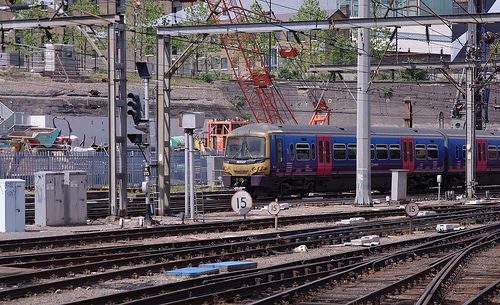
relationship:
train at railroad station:
[221, 125, 496, 196] [3, 3, 493, 300]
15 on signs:
[233, 195, 247, 211] [212, 171, 439, 232]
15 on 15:
[267, 204, 277, 216] [267, 204, 277, 216]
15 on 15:
[406, 204, 416, 218] [406, 204, 416, 218]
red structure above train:
[207, 12, 341, 114] [206, 115, 498, 195]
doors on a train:
[308, 131, 338, 177] [221, 125, 496, 196]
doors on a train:
[400, 129, 420, 171] [221, 125, 496, 196]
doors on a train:
[475, 136, 487, 175] [221, 125, 496, 196]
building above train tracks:
[334, 2, 485, 92] [46, 228, 495, 303]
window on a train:
[295, 143, 311, 160] [221, 125, 496, 196]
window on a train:
[293, 140, 313, 167] [221, 125, 496, 196]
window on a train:
[333, 144, 347, 165] [221, 125, 496, 196]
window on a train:
[349, 144, 358, 164] [221, 125, 496, 196]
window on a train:
[373, 142, 391, 167] [221, 125, 496, 196]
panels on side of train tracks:
[172, 255, 261, 283] [417, 222, 498, 302]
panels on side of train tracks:
[172, 255, 261, 283] [247, 228, 487, 302]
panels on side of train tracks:
[172, 255, 261, 283] [0, 211, 494, 301]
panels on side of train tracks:
[172, 255, 261, 283] [0, 193, 414, 276]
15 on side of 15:
[233, 195, 247, 211] [233, 195, 247, 211]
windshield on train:
[224, 135, 265, 159] [221, 125, 496, 196]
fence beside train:
[3, 147, 215, 189] [221, 125, 496, 196]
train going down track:
[221, 125, 496, 196] [26, 182, 498, 222]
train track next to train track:
[4, 199, 499, 302] [67, 219, 245, 253]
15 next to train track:
[233, 195, 247, 211] [169, 223, 249, 260]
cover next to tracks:
[169, 269, 210, 275] [68, 204, 495, 304]